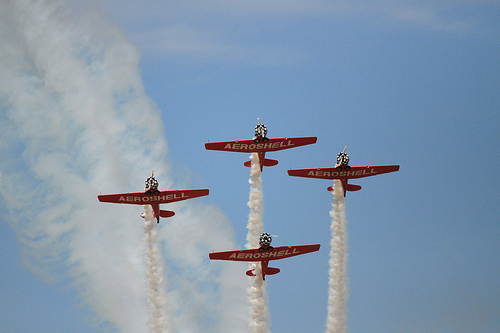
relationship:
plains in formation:
[89, 103, 434, 314] [59, 92, 446, 304]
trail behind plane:
[321, 174, 360, 323] [281, 143, 408, 239]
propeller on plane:
[251, 109, 271, 139] [95, 107, 437, 301]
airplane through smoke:
[203, 226, 327, 287] [236, 143, 298, 323]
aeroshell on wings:
[219, 136, 302, 160] [203, 133, 331, 169]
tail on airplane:
[238, 265, 287, 291] [198, 221, 339, 294]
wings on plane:
[307, 163, 393, 179] [271, 147, 439, 214]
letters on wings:
[304, 168, 384, 183] [307, 163, 393, 179]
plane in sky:
[109, 159, 232, 286] [24, 22, 353, 299]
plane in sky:
[281, 142, 410, 204] [10, 36, 449, 324]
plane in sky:
[279, 145, 413, 217] [76, 40, 476, 293]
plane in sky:
[193, 112, 306, 176] [33, 47, 498, 317]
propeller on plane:
[251, 115, 271, 142] [204, 123, 340, 225]